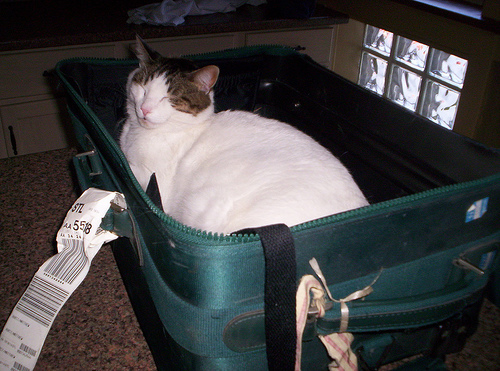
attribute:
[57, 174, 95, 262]
tag — black, white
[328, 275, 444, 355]
strap — dark, blue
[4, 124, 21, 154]
handle — little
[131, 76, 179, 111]
eyes — closed